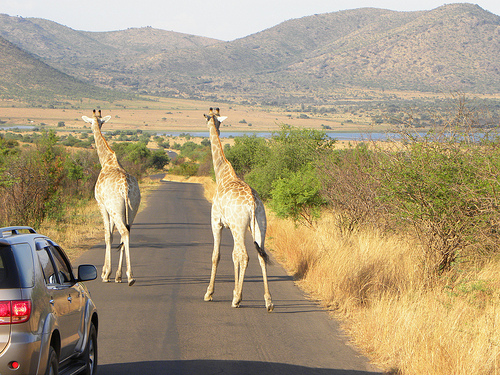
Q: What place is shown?
A: It is a road.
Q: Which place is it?
A: It is a road.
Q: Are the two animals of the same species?
A: Yes, all the animals are giraffes.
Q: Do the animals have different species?
A: No, all the animals are giraffes.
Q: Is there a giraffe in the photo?
A: Yes, there is a giraffe.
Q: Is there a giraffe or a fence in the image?
A: Yes, there is a giraffe.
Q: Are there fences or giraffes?
A: Yes, there is a giraffe.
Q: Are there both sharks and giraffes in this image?
A: No, there is a giraffe but no sharks.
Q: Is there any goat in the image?
A: No, there are no goats.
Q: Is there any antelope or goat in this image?
A: No, there are no goats or antelopes.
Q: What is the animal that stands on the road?
A: The animal is a giraffe.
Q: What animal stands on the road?
A: The animal is a giraffe.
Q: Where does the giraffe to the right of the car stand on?
A: The giraffe stands on the road.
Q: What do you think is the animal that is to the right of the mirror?
A: The animal is a giraffe.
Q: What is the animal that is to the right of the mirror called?
A: The animal is a giraffe.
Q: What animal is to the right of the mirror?
A: The animal is a giraffe.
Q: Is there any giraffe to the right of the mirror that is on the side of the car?
A: Yes, there is a giraffe to the right of the mirror.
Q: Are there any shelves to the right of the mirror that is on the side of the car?
A: No, there is a giraffe to the right of the mirror.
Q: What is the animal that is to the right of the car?
A: The animal is a giraffe.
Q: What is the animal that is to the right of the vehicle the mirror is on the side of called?
A: The animal is a giraffe.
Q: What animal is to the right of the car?
A: The animal is a giraffe.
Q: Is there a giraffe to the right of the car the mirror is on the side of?
A: Yes, there is a giraffe to the right of the car.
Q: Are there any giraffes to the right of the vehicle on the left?
A: Yes, there is a giraffe to the right of the car.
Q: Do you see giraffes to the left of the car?
A: No, the giraffe is to the right of the car.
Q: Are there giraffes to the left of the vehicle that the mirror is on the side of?
A: No, the giraffe is to the right of the car.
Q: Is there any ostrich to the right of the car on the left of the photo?
A: No, there is a giraffe to the right of the car.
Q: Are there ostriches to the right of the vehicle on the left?
A: No, there is a giraffe to the right of the car.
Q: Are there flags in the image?
A: No, there are no flags.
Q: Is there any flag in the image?
A: No, there are no flags.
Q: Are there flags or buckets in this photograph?
A: No, there are no flags or buckets.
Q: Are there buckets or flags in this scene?
A: No, there are no flags or buckets.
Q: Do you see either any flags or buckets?
A: No, there are no flags or buckets.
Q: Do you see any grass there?
A: Yes, there is grass.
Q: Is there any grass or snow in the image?
A: Yes, there is grass.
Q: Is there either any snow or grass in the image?
A: Yes, there is grass.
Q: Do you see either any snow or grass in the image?
A: Yes, there is grass.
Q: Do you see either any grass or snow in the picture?
A: Yes, there is grass.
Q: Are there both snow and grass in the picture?
A: No, there is grass but no snow.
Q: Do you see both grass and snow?
A: No, there is grass but no snow.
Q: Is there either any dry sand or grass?
A: Yes, there is dry grass.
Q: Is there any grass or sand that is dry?
A: Yes, the grass is dry.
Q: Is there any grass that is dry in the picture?
A: Yes, there is dry grass.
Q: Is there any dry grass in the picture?
A: Yes, there is dry grass.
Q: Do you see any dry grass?
A: Yes, there is dry grass.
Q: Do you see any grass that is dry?
A: Yes, there is grass that is dry.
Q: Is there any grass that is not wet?
A: Yes, there is dry grass.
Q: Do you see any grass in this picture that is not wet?
A: Yes, there is dry grass.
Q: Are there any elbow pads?
A: No, there are no elbow pads.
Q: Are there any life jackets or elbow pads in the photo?
A: No, there are no elbow pads or life jackets.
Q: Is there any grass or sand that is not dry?
A: No, there is grass but it is dry.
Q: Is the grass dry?
A: Yes, the grass is dry.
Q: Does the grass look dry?
A: Yes, the grass is dry.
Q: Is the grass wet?
A: No, the grass is dry.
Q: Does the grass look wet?
A: No, the grass is dry.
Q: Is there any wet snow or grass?
A: No, there is grass but it is dry.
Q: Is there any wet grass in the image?
A: No, there is grass but it is dry.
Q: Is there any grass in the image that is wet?
A: No, there is grass but it is dry.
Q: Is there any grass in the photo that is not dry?
A: No, there is grass but it is dry.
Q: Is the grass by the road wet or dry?
A: The grass is dry.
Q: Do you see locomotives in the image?
A: No, there are no locomotives.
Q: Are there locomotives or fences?
A: No, there are no locomotives or fences.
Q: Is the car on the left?
A: Yes, the car is on the left of the image.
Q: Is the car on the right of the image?
A: No, the car is on the left of the image.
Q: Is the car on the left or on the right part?
A: The car is on the left of the image.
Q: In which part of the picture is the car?
A: The car is on the left of the image.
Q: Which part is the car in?
A: The car is on the left of the image.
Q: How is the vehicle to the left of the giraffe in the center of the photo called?
A: The vehicle is a car.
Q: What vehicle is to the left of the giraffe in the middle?
A: The vehicle is a car.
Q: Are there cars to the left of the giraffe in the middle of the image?
A: Yes, there is a car to the left of the giraffe.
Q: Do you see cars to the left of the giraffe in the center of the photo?
A: Yes, there is a car to the left of the giraffe.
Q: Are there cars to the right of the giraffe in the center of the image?
A: No, the car is to the left of the giraffe.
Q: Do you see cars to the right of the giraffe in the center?
A: No, the car is to the left of the giraffe.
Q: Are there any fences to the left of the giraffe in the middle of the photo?
A: No, there is a car to the left of the giraffe.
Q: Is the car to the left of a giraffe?
A: Yes, the car is to the left of a giraffe.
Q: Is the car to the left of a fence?
A: No, the car is to the left of a giraffe.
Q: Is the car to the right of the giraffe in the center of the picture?
A: No, the car is to the left of the giraffe.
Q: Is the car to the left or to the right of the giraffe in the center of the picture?
A: The car is to the left of the giraffe.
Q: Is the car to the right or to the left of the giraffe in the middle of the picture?
A: The car is to the left of the giraffe.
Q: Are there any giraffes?
A: Yes, there is a giraffe.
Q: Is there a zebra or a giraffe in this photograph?
A: Yes, there is a giraffe.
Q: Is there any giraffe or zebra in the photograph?
A: Yes, there is a giraffe.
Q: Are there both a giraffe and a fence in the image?
A: No, there is a giraffe but no fences.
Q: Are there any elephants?
A: No, there are no elephants.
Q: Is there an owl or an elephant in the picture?
A: No, there are no elephants or owls.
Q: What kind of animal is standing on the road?
A: The animal is a giraffe.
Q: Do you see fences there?
A: No, there are no fences.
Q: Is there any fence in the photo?
A: No, there are no fences.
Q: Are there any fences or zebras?
A: No, there are no fences or zebras.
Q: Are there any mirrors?
A: Yes, there is a mirror.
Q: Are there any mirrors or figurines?
A: Yes, there is a mirror.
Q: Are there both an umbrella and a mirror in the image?
A: No, there is a mirror but no umbrellas.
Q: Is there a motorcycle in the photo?
A: No, there are no motorcycles.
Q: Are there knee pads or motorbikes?
A: No, there are no motorbikes or knee pads.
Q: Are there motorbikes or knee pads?
A: No, there are no motorbikes or knee pads.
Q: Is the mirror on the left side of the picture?
A: Yes, the mirror is on the left of the image.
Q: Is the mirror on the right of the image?
A: No, the mirror is on the left of the image.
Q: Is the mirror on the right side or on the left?
A: The mirror is on the left of the image.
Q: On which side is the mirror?
A: The mirror is on the left of the image.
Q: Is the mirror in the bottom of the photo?
A: Yes, the mirror is in the bottom of the image.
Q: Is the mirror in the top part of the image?
A: No, the mirror is in the bottom of the image.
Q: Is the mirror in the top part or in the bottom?
A: The mirror is in the bottom of the image.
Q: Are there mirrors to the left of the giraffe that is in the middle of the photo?
A: Yes, there is a mirror to the left of the giraffe.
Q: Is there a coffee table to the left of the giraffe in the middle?
A: No, there is a mirror to the left of the giraffe.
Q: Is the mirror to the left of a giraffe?
A: Yes, the mirror is to the left of a giraffe.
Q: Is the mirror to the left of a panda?
A: No, the mirror is to the left of a giraffe.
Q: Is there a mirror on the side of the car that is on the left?
A: Yes, there is a mirror on the side of the car.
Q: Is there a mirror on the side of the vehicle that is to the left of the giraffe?
A: Yes, there is a mirror on the side of the car.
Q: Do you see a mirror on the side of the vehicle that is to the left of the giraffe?
A: Yes, there is a mirror on the side of the car.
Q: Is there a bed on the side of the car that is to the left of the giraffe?
A: No, there is a mirror on the side of the car.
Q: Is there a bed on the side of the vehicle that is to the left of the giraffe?
A: No, there is a mirror on the side of the car.